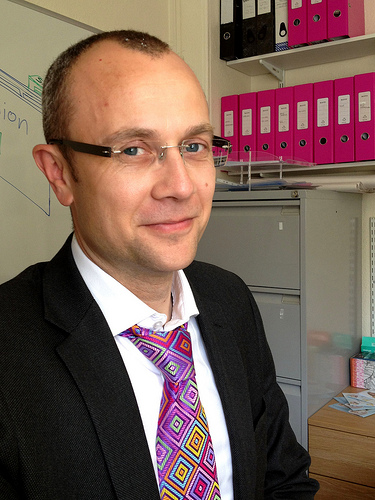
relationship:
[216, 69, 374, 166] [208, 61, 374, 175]
files are on shelf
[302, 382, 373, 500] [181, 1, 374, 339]
table near wall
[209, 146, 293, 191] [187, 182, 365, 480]
racks are on cupboard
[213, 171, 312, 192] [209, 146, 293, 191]
files in rack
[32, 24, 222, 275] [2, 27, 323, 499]
head on person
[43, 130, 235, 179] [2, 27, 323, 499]
glasses on man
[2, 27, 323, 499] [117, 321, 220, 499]
man has tie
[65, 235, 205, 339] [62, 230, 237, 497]
collar on shirt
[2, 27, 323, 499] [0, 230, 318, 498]
man wearing jacket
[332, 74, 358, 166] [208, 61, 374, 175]
binder on shelf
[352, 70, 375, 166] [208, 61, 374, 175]
binder on shelf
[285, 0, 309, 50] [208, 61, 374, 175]
binder on shelf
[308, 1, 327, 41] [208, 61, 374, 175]
binder on shelf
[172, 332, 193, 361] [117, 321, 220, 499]
color on tie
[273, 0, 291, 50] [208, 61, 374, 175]
file on shelf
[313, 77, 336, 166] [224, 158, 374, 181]
binder on shelf